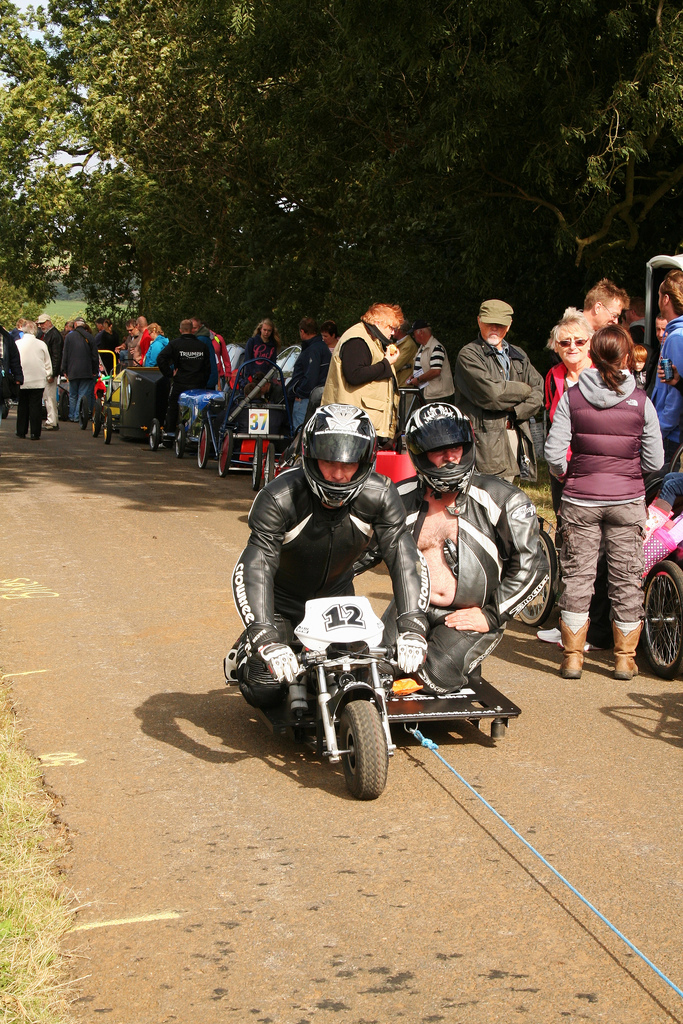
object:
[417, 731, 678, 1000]
cord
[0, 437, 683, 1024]
road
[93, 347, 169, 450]
vehicles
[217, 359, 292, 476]
vehicles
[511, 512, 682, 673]
vehicle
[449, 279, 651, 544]
people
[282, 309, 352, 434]
people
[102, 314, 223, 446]
people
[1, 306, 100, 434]
people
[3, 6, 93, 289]
trees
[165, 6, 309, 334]
trees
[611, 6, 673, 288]
trees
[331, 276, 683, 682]
people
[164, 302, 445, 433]
people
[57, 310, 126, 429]
people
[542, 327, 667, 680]
woman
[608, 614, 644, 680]
boots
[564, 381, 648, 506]
vest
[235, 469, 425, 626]
jacket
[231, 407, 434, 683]
man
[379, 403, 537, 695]
man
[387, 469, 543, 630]
jacket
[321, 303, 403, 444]
person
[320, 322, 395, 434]
vest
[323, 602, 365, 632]
12 number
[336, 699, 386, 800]
wheel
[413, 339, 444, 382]
shirt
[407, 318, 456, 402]
man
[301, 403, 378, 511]
helmet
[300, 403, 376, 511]
head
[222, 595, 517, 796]
bike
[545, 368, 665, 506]
coat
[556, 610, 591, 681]
boots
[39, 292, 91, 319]
grass